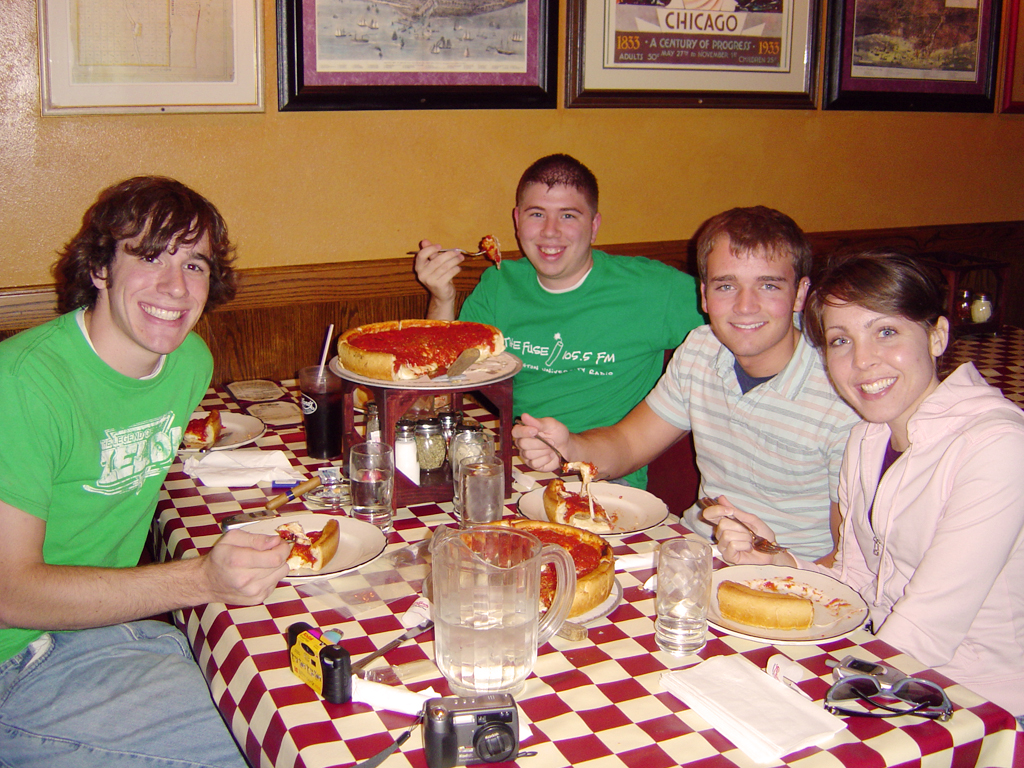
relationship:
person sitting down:
[810, 267, 1020, 726] [48, 645, 260, 768]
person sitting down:
[539, 206, 847, 590] [153, 645, 279, 768]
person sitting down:
[422, 152, 711, 485] [156, 630, 243, 723]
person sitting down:
[8, 175, 294, 767] [162, 594, 294, 768]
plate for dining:
[229, 513, 394, 581] [283, 518, 377, 760]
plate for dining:
[516, 472, 663, 548] [249, 596, 364, 768]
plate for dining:
[703, 554, 865, 638] [290, 436, 418, 651]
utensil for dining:
[703, 485, 781, 552] [285, 529, 398, 690]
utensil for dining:
[408, 236, 498, 275] [240, 544, 334, 679]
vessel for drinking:
[640, 535, 708, 660] [406, 619, 625, 676]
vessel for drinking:
[349, 446, 403, 527] [421, 561, 499, 768]